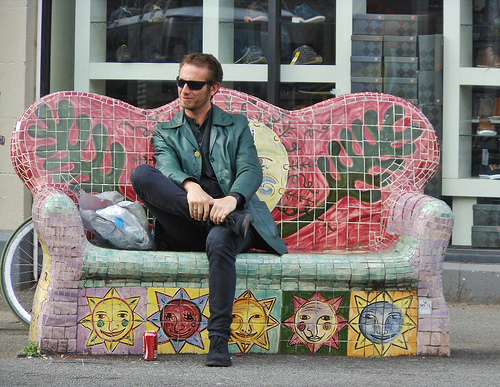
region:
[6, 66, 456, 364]
A MULTICOLORED PAINTED BENCH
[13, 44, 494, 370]
A MAN SITTING ON A BENCH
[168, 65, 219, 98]
A PAIR OF SUNGLASSES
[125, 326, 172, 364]
A CAN OF COKE ON THE GROUND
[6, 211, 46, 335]
A BIKE WHEEL BEHIND THE BENCH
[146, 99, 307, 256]
A MANS GREEN JACKET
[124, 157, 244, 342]
A PAIR OF BLACK JEANS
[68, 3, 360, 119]
A STOREFRONT WINDOW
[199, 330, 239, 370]
A MANS BLACK SHOE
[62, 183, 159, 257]
PLASTIC BAGS ON A BENCH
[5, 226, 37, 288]
their is a tyre on the background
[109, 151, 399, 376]
a guy is sitted on the bench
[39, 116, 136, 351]
this bench is very colourful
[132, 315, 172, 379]
this is a coca cola can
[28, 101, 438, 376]
this an outdoor image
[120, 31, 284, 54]
this are tinted windows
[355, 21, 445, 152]
this are stock boxes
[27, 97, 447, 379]
what a lovely bench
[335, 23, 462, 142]
this are grey walls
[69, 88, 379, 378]
a very nice shit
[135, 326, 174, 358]
the can is red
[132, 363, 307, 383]
the ground is grey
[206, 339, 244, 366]
the shoes are black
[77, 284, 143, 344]
the sun has a smiley face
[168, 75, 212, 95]
the sun glasses are black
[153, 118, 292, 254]
the leather jacket is green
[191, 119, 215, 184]
the shirt is black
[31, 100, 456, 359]
the sofa has square tiles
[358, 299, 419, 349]
the sun has a blue face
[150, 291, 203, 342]
the sun has a red face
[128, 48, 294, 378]
Man is sitting on a bench.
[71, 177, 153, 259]
Bags lying on bench.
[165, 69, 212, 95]
Man is wearing sunglasses.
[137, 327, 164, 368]
Can on ground in front of bench.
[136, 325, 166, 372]
Can is red and white.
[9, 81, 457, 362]
Bench has been painted.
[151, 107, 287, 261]
Man is wearing a jacket.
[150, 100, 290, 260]
Jacket is green leather.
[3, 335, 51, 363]
Weed growing by corner of bench.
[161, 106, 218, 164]
Man is wearing necklace.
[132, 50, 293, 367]
Man sitting on outside sofa.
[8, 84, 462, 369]
Red, blue and pink art decorated sofa.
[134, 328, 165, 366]
Coca cola can sitting on ground.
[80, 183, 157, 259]
Plastic bag sitting on sofa beside man.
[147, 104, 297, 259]
Man wearing blue leather jacket.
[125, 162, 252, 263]
Man sitting with leg crossed.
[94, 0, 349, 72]
Windows in front of building.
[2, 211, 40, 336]
Part of a bicycle tire.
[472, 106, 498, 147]
Brown shoe on display in window.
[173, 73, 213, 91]
Man wearing black sunglasses over eyes.